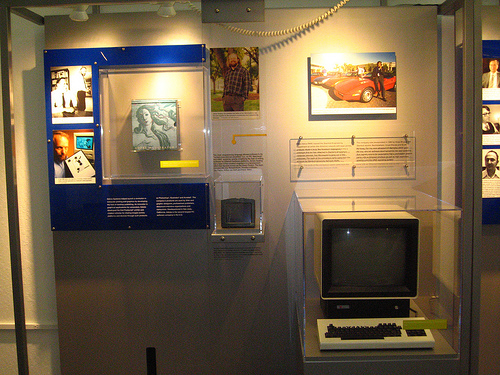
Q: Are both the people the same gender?
A: No, they are both male and female.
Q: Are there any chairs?
A: No, there are no chairs.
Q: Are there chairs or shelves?
A: No, there are no chairs or shelves.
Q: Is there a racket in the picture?
A: No, there are no rackets.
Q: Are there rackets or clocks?
A: No, there are no rackets or clocks.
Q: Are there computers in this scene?
A: Yes, there is a computer.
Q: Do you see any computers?
A: Yes, there is a computer.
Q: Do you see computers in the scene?
A: Yes, there is a computer.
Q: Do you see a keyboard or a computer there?
A: Yes, there is a computer.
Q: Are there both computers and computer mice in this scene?
A: No, there is a computer but no computer mice.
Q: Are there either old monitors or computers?
A: Yes, there is an old computer.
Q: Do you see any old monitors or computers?
A: Yes, there is an old computer.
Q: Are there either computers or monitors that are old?
A: Yes, the computer is old.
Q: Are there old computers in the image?
A: Yes, there is an old computer.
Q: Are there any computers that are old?
A: Yes, there is a computer that is old.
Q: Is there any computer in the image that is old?
A: Yes, there is a computer that is old.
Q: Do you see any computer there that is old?
A: Yes, there is a computer that is old.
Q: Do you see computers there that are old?
A: Yes, there is a computer that is old.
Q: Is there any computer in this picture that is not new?
A: Yes, there is a old computer.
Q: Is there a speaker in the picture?
A: No, there are no speakers.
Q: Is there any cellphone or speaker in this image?
A: No, there are no speakers or cell phones.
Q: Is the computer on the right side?
A: Yes, the computer is on the right of the image.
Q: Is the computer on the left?
A: No, the computer is on the right of the image.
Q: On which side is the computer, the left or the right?
A: The computer is on the right of the image.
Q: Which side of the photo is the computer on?
A: The computer is on the right of the image.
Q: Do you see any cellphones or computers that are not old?
A: No, there is a computer but it is old.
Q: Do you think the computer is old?
A: Yes, the computer is old.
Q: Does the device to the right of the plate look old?
A: Yes, the computer is old.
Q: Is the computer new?
A: No, the computer is old.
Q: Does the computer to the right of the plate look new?
A: No, the computer is old.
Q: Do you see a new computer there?
A: No, there is a computer but it is old.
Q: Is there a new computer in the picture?
A: No, there is a computer but it is old.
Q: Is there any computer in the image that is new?
A: No, there is a computer but it is old.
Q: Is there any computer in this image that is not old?
A: No, there is a computer but it is old.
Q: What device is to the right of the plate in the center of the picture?
A: The device is a computer.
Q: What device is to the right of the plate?
A: The device is a computer.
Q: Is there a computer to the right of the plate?
A: Yes, there is a computer to the right of the plate.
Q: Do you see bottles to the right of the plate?
A: No, there is a computer to the right of the plate.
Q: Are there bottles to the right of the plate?
A: No, there is a computer to the right of the plate.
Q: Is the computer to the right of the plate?
A: Yes, the computer is to the right of the plate.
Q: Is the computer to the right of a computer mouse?
A: No, the computer is to the right of the plate.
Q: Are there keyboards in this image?
A: Yes, there is a keyboard.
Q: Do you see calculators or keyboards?
A: Yes, there is a keyboard.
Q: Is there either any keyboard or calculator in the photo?
A: Yes, there is a keyboard.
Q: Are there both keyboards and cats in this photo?
A: No, there is a keyboard but no cats.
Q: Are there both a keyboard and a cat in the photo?
A: No, there is a keyboard but no cats.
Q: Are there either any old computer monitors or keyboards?
A: Yes, there is an old keyboard.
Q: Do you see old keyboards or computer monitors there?
A: Yes, there is an old keyboard.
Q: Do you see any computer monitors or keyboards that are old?
A: Yes, the keyboard is old.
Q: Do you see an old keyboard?
A: Yes, there is an old keyboard.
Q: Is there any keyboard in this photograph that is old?
A: Yes, there is a keyboard that is old.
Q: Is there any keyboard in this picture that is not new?
A: Yes, there is a old keyboard.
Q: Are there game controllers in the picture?
A: No, there are no game controllers.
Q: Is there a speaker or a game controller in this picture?
A: No, there are no game controllers or speakers.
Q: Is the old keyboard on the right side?
A: Yes, the keyboard is on the right of the image.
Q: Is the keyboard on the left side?
A: No, the keyboard is on the right of the image.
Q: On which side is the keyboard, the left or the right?
A: The keyboard is on the right of the image.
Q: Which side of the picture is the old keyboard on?
A: The keyboard is on the right of the image.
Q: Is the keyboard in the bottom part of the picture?
A: Yes, the keyboard is in the bottom of the image.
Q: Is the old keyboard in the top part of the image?
A: No, the keyboard is in the bottom of the image.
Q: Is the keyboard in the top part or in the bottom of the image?
A: The keyboard is in the bottom of the image.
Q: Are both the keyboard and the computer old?
A: Yes, both the keyboard and the computer are old.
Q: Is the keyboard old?
A: Yes, the keyboard is old.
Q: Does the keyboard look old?
A: Yes, the keyboard is old.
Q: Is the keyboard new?
A: No, the keyboard is old.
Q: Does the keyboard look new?
A: No, the keyboard is old.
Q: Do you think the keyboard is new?
A: No, the keyboard is old.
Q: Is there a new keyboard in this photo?
A: No, there is a keyboard but it is old.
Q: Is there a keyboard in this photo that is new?
A: No, there is a keyboard but it is old.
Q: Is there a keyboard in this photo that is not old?
A: No, there is a keyboard but it is old.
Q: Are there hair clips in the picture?
A: No, there are no hair clips.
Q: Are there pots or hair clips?
A: No, there are no hair clips or pots.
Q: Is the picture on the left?
A: Yes, the picture is on the left of the image.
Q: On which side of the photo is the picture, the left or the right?
A: The picture is on the left of the image.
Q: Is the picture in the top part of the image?
A: Yes, the picture is in the top of the image.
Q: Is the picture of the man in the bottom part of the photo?
A: No, the picture is in the top of the image.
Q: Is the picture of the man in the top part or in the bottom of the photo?
A: The picture is in the top of the image.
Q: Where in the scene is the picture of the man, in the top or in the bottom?
A: The picture is in the top of the image.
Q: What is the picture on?
A: The picture is on the wall.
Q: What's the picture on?
A: The picture is on the wall.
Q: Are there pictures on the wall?
A: Yes, there is a picture on the wall.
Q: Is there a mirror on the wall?
A: No, there is a picture on the wall.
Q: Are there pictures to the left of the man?
A: Yes, there is a picture to the left of the man.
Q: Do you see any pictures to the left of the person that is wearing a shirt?
A: Yes, there is a picture to the left of the man.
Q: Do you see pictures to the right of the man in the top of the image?
A: No, the picture is to the left of the man.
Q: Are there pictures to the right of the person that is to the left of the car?
A: No, the picture is to the left of the man.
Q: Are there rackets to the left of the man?
A: No, there is a picture to the left of the man.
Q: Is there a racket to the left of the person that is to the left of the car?
A: No, there is a picture to the left of the man.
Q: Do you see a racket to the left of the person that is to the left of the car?
A: No, there is a picture to the left of the man.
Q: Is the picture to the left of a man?
A: Yes, the picture is to the left of a man.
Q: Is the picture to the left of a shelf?
A: No, the picture is to the left of a man.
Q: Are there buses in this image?
A: No, there are no buses.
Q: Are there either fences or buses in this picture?
A: No, there are no buses or fences.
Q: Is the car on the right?
A: Yes, the car is on the right of the image.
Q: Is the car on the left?
A: No, the car is on the right of the image.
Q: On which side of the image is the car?
A: The car is on the right of the image.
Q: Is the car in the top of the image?
A: Yes, the car is in the top of the image.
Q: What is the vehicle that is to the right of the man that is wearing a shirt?
A: The vehicle is a car.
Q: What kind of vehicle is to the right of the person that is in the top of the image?
A: The vehicle is a car.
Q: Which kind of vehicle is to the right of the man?
A: The vehicle is a car.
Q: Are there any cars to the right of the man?
A: Yes, there is a car to the right of the man.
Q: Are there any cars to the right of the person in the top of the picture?
A: Yes, there is a car to the right of the man.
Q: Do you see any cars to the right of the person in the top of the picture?
A: Yes, there is a car to the right of the man.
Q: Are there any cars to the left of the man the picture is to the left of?
A: No, the car is to the right of the man.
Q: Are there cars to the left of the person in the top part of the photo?
A: No, the car is to the right of the man.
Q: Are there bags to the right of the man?
A: No, there is a car to the right of the man.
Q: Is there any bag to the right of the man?
A: No, there is a car to the right of the man.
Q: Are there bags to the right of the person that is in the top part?
A: No, there is a car to the right of the man.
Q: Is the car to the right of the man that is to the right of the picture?
A: Yes, the car is to the right of the man.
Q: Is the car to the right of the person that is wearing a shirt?
A: Yes, the car is to the right of the man.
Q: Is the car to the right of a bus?
A: No, the car is to the right of the man.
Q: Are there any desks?
A: No, there are no desks.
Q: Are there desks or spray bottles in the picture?
A: No, there are no desks or spray bottles.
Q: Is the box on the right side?
A: Yes, the box is on the right of the image.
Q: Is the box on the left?
A: No, the box is on the right of the image.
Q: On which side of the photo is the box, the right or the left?
A: The box is on the right of the image.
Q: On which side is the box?
A: The box is on the right of the image.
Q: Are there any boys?
A: No, there are no boys.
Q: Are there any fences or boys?
A: No, there are no boys or fences.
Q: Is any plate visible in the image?
A: Yes, there is a plate.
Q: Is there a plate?
A: Yes, there is a plate.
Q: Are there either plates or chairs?
A: Yes, there is a plate.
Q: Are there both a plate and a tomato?
A: No, there is a plate but no tomatoes.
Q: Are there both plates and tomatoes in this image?
A: No, there is a plate but no tomatoes.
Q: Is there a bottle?
A: No, there are no bottles.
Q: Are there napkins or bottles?
A: No, there are no bottles or napkins.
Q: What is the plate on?
A: The plate is on the wall.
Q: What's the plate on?
A: The plate is on the wall.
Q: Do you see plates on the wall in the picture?
A: Yes, there is a plate on the wall.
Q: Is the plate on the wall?
A: Yes, the plate is on the wall.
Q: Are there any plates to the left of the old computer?
A: Yes, there is a plate to the left of the computer.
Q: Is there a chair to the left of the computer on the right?
A: No, there is a plate to the left of the computer.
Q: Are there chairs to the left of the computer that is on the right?
A: No, there is a plate to the left of the computer.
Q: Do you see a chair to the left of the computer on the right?
A: No, there is a plate to the left of the computer.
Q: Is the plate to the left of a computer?
A: Yes, the plate is to the left of a computer.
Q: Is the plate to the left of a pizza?
A: No, the plate is to the left of a computer.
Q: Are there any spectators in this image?
A: No, there are no spectators.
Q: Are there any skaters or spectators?
A: No, there are no spectators or skaters.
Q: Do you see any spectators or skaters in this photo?
A: No, there are no spectators or skaters.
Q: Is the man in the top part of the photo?
A: Yes, the man is in the top of the image.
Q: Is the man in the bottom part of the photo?
A: No, the man is in the top of the image.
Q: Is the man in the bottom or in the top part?
A: The man is in the top of the image.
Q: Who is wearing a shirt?
A: The man is wearing a shirt.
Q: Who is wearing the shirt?
A: The man is wearing a shirt.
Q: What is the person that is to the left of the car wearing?
A: The man is wearing a shirt.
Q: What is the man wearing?
A: The man is wearing a shirt.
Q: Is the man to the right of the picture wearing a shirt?
A: Yes, the man is wearing a shirt.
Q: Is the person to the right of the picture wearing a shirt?
A: Yes, the man is wearing a shirt.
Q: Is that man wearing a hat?
A: No, the man is wearing a shirt.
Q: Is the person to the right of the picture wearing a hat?
A: No, the man is wearing a shirt.